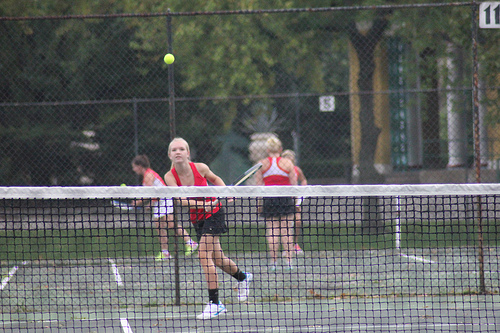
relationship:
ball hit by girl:
[163, 53, 175, 65] [162, 137, 254, 319]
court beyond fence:
[0, 246, 499, 331] [0, 178, 482, 331]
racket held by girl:
[205, 162, 264, 212] [156, 133, 258, 323]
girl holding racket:
[162, 136, 252, 320] [210, 164, 264, 207]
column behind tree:
[444, 44, 468, 167] [127, 0, 498, 234]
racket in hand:
[198, 158, 280, 224] [160, 174, 233, 215]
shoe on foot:
[174, 297, 239, 322] [194, 299, 225, 319]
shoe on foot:
[235, 272, 253, 304] [179, 276, 243, 316]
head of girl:
[165, 137, 189, 164] [159, 122, 278, 319]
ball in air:
[151, 42, 193, 75] [12, 10, 494, 224]